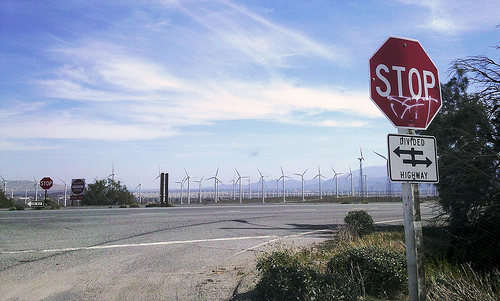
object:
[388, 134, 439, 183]
sign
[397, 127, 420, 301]
pole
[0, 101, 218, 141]
cloud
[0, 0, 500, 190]
sky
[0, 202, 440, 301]
street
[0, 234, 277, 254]
line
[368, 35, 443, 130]
sign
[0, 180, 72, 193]
mountain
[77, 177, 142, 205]
bush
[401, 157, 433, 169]
arrow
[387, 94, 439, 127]
graffiti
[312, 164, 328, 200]
turbine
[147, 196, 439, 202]
field